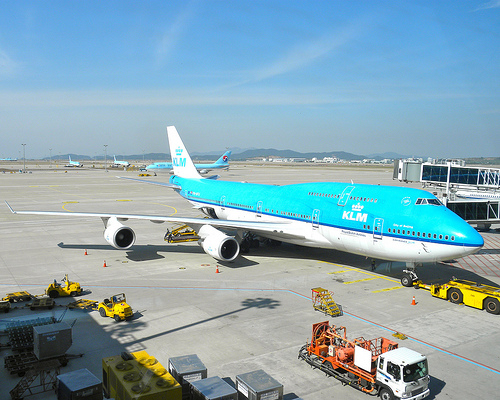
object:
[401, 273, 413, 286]
gear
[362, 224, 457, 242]
windows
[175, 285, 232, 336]
ground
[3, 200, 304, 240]
wing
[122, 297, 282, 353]
shadow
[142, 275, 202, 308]
ground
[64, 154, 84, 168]
airplane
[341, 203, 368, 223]
branding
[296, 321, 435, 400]
cab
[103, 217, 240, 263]
engines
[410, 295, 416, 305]
cone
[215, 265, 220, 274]
cone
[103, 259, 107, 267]
cone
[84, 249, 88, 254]
cone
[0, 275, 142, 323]
yellow luggage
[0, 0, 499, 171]
sky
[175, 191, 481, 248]
stripe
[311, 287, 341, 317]
stairs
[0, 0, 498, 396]
outdoors scene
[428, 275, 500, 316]
carts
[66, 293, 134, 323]
carts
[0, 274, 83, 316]
carts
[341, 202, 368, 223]
lettering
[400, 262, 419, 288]
landing gear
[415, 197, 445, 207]
windows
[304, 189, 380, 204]
windows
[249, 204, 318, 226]
windows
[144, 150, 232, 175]
airplane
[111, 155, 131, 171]
airplane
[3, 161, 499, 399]
tarmack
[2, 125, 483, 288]
airplane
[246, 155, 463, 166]
homes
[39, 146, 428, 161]
mountain range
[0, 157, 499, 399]
tarmac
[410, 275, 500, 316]
luggage carrier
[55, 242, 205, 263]
shadow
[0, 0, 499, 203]
background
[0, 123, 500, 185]
distance